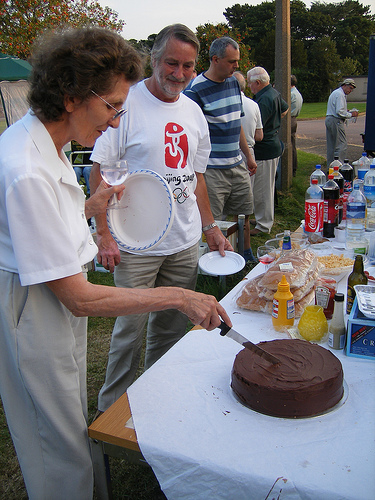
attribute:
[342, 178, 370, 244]
bottle — big, water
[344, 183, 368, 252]
bottle — tall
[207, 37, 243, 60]
hair — grey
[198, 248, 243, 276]
plate — small, white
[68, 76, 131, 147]
face — woman's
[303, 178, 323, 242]
bottle — coke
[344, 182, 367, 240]
bottle — water, clear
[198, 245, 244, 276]
plate — white, plain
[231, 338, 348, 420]
cake — chocolate, frosted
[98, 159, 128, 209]
glass — wine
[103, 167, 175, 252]
plate — white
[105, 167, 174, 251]
trim — blue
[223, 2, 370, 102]
trees — green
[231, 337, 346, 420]
frosting — chocolate